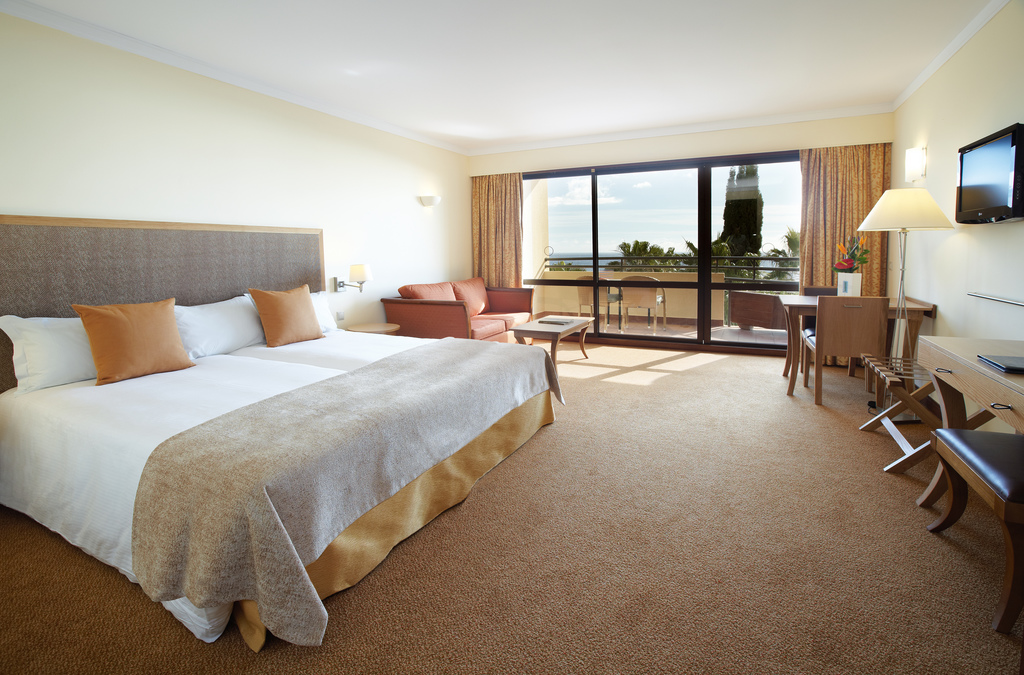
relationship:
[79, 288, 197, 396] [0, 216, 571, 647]
pillow on bed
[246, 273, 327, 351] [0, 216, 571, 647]
pillow on bed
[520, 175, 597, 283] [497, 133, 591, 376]
glass inside window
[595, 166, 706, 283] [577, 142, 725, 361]
glass inside window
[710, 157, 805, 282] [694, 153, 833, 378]
glass inside window